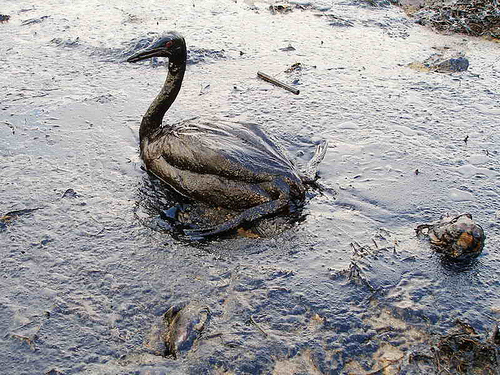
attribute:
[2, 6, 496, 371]
water — oily